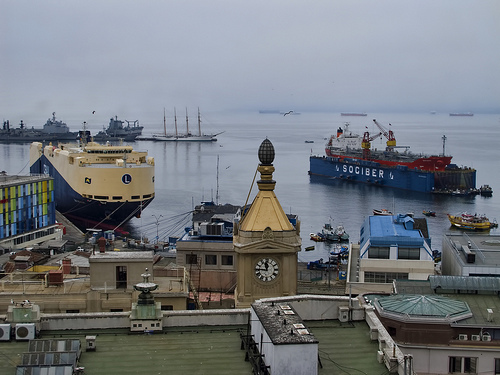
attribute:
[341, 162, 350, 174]
letter — white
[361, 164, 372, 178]
letter — white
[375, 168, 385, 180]
letter — white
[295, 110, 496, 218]
ship — blue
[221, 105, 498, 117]
land — distant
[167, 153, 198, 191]
water — black, calm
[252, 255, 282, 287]
clock — white, black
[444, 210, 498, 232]
boat — yellow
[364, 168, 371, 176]
letter — white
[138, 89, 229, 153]
boat — white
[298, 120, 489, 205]
boat — large, blue, red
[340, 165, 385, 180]
letter — white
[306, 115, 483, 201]
ship — large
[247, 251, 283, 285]
clock — large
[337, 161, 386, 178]
letters — white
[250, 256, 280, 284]
face — white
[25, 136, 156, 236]
boat — tan, blue